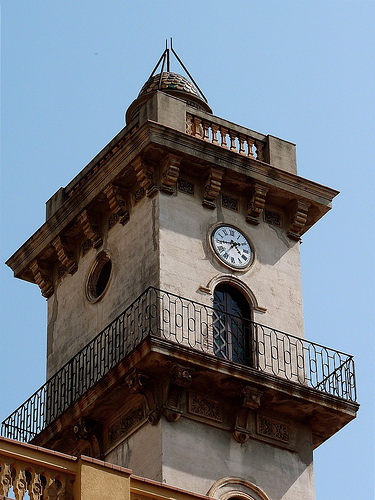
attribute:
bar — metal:
[253, 322, 264, 371]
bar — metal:
[348, 351, 357, 402]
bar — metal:
[146, 285, 158, 333]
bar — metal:
[124, 305, 135, 353]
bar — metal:
[269, 328, 282, 375]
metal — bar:
[148, 281, 357, 358]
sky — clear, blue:
[1, 2, 371, 498]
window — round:
[85, 250, 113, 303]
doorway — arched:
[207, 280, 258, 364]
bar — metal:
[151, 285, 352, 356]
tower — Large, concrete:
[1, 36, 358, 497]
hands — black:
[218, 237, 244, 253]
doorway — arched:
[206, 473, 287, 498]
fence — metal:
[2, 283, 355, 441]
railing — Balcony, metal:
[2, 285, 152, 443]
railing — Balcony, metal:
[151, 286, 355, 401]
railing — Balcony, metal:
[312, 355, 354, 401]